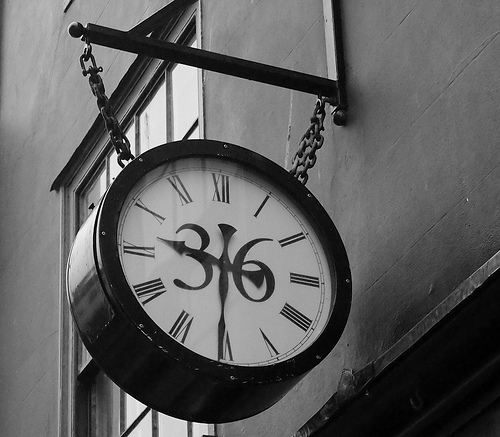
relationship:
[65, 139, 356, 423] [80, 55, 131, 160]
clock held up by chain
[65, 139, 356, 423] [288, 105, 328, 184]
clock being held up by chain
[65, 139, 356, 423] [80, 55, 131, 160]
clock being held up by chain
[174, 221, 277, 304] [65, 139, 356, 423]
36 on clock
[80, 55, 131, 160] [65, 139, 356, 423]
chain holding clock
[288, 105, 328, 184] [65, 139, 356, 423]
chain holding clock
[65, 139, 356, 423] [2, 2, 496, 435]
clock hanging on building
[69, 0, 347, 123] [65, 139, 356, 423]
metal bracket holding clock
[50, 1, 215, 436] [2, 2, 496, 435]
window in building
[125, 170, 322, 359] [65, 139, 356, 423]
roman numerals on clock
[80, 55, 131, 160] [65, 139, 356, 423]
chain attached to clock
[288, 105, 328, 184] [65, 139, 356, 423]
chain attached to clock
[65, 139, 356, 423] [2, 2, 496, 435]
clock on building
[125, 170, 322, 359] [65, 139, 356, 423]
roman numerals on a clock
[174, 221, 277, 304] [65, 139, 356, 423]
36 on a clock